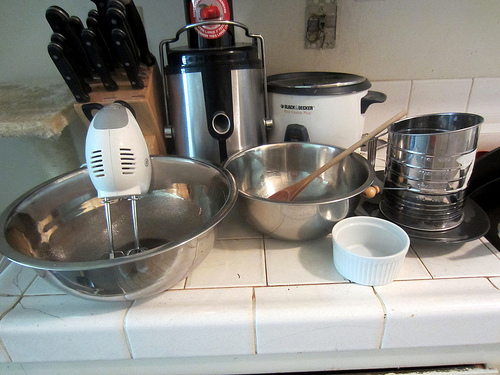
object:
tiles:
[253, 281, 385, 354]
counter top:
[0, 147, 499, 329]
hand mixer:
[84, 102, 153, 277]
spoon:
[266, 108, 409, 201]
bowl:
[0, 153, 238, 301]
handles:
[110, 28, 144, 89]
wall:
[0, 0, 499, 152]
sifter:
[378, 110, 485, 231]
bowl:
[331, 215, 411, 286]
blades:
[100, 197, 126, 277]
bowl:
[223, 141, 378, 242]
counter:
[0, 144, 499, 374]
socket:
[302, 1, 338, 49]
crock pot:
[266, 71, 387, 155]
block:
[73, 55, 170, 157]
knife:
[47, 43, 91, 104]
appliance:
[159, 19, 273, 166]